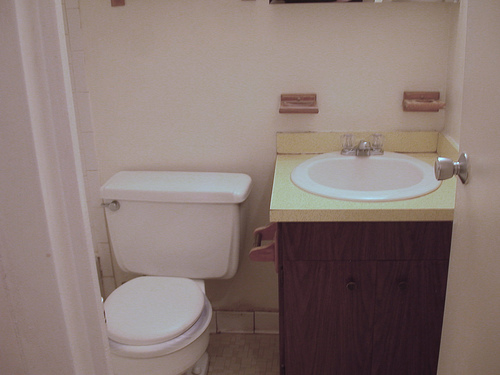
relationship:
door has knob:
[468, 40, 499, 159] [432, 152, 474, 191]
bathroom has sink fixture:
[29, 59, 436, 373] [283, 133, 436, 211]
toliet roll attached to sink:
[246, 220, 272, 264] [296, 149, 433, 199]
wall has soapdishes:
[135, 28, 239, 96] [279, 79, 447, 117]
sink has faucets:
[296, 149, 433, 199] [357, 138, 374, 160]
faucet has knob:
[333, 133, 392, 156] [432, 152, 474, 191]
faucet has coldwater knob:
[333, 133, 392, 156] [337, 130, 355, 155]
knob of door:
[432, 152, 474, 191] [468, 40, 499, 159]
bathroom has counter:
[39, 40, 473, 257] [279, 193, 307, 216]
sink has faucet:
[296, 149, 433, 199] [333, 133, 392, 156]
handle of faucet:
[451, 154, 474, 184] [333, 133, 392, 156]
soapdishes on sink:
[279, 79, 447, 117] [296, 149, 433, 199]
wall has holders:
[135, 28, 239, 96] [275, 90, 325, 103]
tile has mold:
[239, 308, 256, 326] [243, 307, 260, 313]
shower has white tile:
[15, 85, 80, 250] [78, 155, 98, 205]